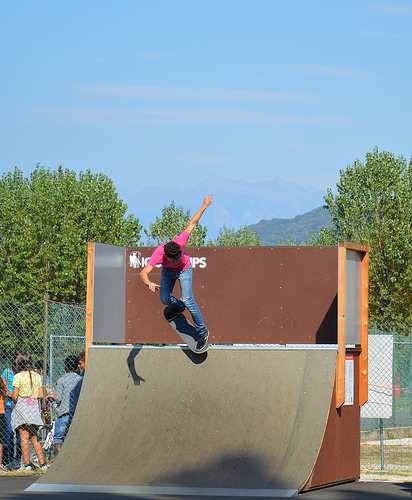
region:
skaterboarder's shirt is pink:
[137, 243, 199, 265]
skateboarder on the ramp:
[147, 249, 229, 363]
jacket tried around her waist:
[11, 393, 50, 438]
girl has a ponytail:
[21, 363, 42, 401]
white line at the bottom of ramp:
[38, 466, 306, 498]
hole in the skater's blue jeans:
[176, 284, 206, 309]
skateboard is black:
[169, 301, 244, 378]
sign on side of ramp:
[340, 348, 372, 409]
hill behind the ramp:
[246, 182, 311, 236]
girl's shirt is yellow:
[23, 371, 35, 412]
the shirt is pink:
[138, 229, 207, 294]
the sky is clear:
[0, 0, 410, 227]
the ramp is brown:
[24, 324, 371, 498]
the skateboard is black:
[155, 292, 235, 380]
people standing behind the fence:
[2, 330, 106, 488]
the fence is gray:
[0, 298, 102, 479]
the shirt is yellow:
[10, 356, 53, 412]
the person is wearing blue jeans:
[151, 259, 220, 352]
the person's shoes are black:
[147, 296, 217, 357]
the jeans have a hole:
[172, 291, 212, 322]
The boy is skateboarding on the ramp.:
[143, 198, 214, 369]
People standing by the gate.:
[0, 347, 100, 470]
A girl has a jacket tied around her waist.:
[9, 387, 54, 429]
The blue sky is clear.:
[110, 123, 340, 200]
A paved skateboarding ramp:
[88, 347, 306, 475]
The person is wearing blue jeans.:
[135, 269, 227, 337]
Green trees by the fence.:
[13, 171, 116, 299]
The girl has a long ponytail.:
[23, 363, 45, 389]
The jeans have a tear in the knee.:
[174, 285, 203, 313]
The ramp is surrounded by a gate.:
[25, 294, 85, 440]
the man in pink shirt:
[120, 223, 281, 382]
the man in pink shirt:
[97, 258, 229, 364]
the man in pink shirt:
[123, 207, 212, 320]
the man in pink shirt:
[94, 153, 238, 367]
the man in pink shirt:
[159, 236, 250, 360]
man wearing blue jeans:
[129, 192, 229, 362]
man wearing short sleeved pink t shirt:
[121, 187, 231, 299]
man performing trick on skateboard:
[134, 182, 221, 357]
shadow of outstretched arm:
[115, 334, 152, 392]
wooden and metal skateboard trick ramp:
[28, 229, 372, 496]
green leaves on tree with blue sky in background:
[1, 146, 131, 241]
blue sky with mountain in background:
[99, 147, 324, 194]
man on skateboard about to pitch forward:
[130, 191, 239, 498]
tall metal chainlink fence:
[369, 327, 410, 483]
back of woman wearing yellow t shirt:
[9, 347, 47, 476]